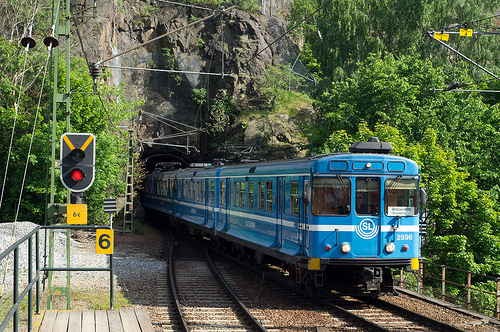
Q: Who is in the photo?
A: No one.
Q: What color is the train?
A: Blue.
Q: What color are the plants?
A: Green.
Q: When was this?
A: Daytime.